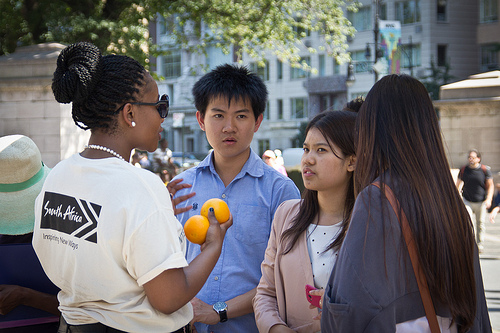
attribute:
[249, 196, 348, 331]
shirt — pink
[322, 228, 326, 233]
dot — black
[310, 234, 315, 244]
dot — black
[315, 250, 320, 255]
dot — black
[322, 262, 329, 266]
dot — black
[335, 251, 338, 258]
dot — black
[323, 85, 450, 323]
person — dark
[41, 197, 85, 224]
letters — white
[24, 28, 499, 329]
man — staring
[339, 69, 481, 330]
black hair — long, straight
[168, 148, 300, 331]
shirt — blue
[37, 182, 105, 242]
picture — black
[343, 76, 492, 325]
hair — long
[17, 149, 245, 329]
tee shirt — black, white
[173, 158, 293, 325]
shirt — blue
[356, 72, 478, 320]
hair — very long